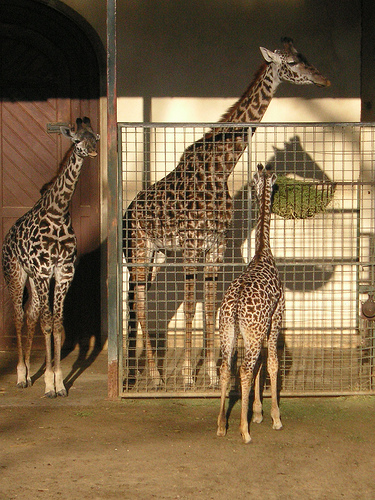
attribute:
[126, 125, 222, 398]
fence — metal, gray, tall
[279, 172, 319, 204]
hay — green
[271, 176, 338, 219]
bucket — green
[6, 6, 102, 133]
door — tall, brown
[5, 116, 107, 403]
giraffe — standing, spotted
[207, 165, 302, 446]
giraffe — brown, baby, young, small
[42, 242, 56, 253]
spot — brown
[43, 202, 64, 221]
spot — brown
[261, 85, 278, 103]
spot — brown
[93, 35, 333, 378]
giraffe — large, tall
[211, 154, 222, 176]
spot — brown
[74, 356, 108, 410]
floor — concrete